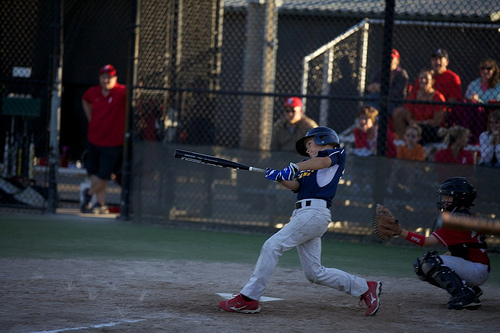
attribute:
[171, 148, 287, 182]
bat — black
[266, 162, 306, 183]
baseball gloves — blue, white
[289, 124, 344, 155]
helmet — protective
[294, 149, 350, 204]
shirt — blue, white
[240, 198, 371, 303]
pants — white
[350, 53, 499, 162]
spectators — sitting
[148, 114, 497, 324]
kids — playing